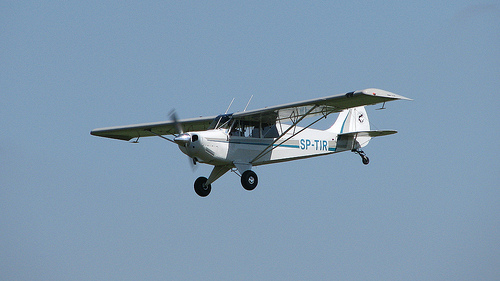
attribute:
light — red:
[367, 87, 384, 102]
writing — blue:
[295, 132, 332, 153]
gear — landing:
[192, 161, 258, 197]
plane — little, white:
[87, 85, 412, 197]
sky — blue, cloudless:
[2, 1, 497, 280]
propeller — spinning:
[155, 102, 222, 167]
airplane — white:
[62, 69, 421, 216]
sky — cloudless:
[39, 42, 124, 108]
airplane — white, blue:
[91, 86, 414, 194]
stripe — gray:
[205, 140, 339, 152]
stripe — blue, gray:
[206, 136, 339, 147]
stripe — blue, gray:
[341, 108, 350, 130]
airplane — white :
[89, 84, 416, 204]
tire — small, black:
[359, 155, 369, 166]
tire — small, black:
[237, 169, 259, 191]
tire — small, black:
[193, 175, 213, 197]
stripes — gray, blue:
[207, 135, 301, 153]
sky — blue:
[7, 4, 483, 83]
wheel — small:
[356, 150, 373, 162]